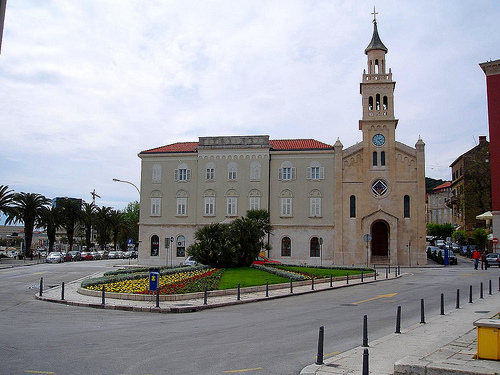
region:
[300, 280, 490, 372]
A row of black posts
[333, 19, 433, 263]
A clock on the front of the building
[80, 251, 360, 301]
The flower bed is in front of the building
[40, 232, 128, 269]
Cars parked on the street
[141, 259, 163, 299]
Blue and yellow sign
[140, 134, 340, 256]
The building has a red roof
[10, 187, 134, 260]
A row of trees on the side walk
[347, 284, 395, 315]
Yellow arrow on the street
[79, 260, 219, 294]
The flowers are yellow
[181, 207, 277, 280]
Large bush in the middle of the flowers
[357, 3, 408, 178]
This is a tower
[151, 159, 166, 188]
This is a window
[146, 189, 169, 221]
This is a window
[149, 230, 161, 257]
This is a window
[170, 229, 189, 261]
This is a window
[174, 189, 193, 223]
This is a window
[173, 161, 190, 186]
This is a window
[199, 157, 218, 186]
This is a window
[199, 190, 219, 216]
This is a window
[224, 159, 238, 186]
This is a window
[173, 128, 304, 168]
the roof is red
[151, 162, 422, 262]
the building has windows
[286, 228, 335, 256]
the window is arched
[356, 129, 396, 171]
clock is on the wall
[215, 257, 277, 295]
the grass is well manicured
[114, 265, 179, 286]
the flowers are yellow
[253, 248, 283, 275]
the car is red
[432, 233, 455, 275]
the cars are parked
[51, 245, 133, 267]
the cars are parked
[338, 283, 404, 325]
the arrow sign is yellow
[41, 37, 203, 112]
Sky is white color.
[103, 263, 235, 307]
Flowers are yellow and red color.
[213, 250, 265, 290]
grass is green color.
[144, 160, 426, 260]
Building wall is brown color.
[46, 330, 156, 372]
Road is grey color.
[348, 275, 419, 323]
Yellow arrow in road.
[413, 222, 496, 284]
cars are parked in sides of the road.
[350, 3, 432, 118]
Cross on top of the tower.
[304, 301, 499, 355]
Poles on sides of the road.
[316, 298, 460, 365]
Poles are grey color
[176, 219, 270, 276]
the bush is large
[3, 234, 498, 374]
THE STREET IS PAVED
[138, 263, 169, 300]
THE SIGN IS BLUE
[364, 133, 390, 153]
THE CLOCK IS BLUE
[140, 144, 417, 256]
THE BUILDING HAS MANY WINDOWS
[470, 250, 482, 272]
THE MAN IS WEARING A RED SHIRT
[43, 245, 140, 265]
THE CARS ARE PARKED ON THE STREET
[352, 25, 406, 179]
THE BUILDING HAS A BELL TOWER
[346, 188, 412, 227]
THE WINDOWS ARE ARCHED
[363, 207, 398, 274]
THE DOOR IS AN ARCHWAY